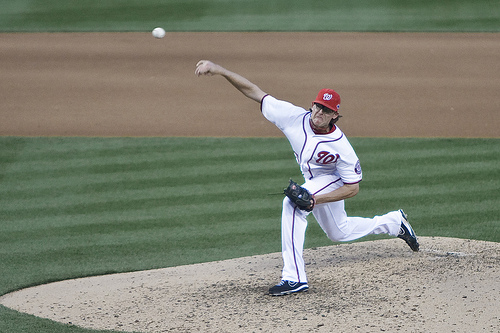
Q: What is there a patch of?
A: Turf.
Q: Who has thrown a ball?
A: The pitcher.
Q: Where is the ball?
A: In mid air.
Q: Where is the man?
A: On the pitcher's mound.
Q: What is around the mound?
A: Grass.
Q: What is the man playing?
A: Baseball.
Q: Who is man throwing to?
A: The hitter.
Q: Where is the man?
A: On a baseball field.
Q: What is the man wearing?
A: A baseball uniform.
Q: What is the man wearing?
A: A baseball uniform.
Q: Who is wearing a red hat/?
A: The baseball player.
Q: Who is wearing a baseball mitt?
A: The baseball player.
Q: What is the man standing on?
A: A pitchers mound.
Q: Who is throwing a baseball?
A: Baseball player.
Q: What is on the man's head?
A: Baseball cap.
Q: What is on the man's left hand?
A: Baseball glove.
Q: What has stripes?
A: The grass.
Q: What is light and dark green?
A: The grass.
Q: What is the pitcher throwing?
A: Ball.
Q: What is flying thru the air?
A: Baseball.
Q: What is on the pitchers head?
A: Red Cap.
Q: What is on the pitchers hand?
A: Baseball glove.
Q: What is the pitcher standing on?
A: A pitching mound.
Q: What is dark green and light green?
A: Grass.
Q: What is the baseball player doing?
A: Throwing a ball.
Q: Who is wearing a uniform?
A: The pitcher.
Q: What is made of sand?
A: Pitching mound.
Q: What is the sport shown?
A: Baseball.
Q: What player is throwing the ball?
A: Pitcher.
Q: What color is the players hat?
A: Red.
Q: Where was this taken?
A: Ballpark.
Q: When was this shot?
A: Night time.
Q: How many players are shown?
A: 1.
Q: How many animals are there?
A: 0.